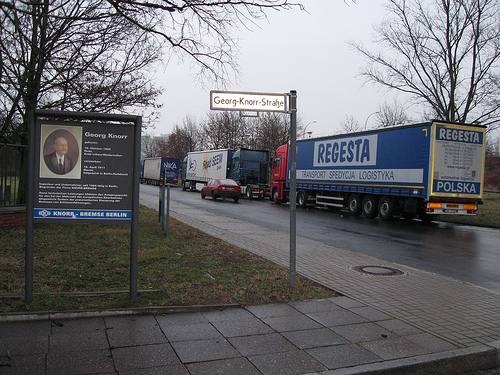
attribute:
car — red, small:
[201, 177, 240, 202]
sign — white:
[211, 90, 297, 286]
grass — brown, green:
[0, 202, 342, 320]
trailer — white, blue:
[287, 119, 487, 200]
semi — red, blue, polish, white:
[270, 145, 433, 222]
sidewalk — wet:
[140, 193, 500, 374]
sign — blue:
[32, 208, 132, 221]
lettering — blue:
[317, 138, 372, 162]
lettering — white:
[439, 128, 481, 144]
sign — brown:
[26, 108, 139, 220]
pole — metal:
[130, 221, 139, 305]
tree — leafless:
[1, 0, 305, 142]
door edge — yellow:
[431, 121, 485, 200]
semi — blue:
[140, 156, 179, 184]